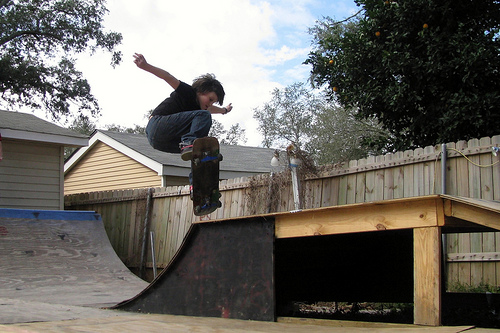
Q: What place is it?
A: It is a yard.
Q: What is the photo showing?
A: It is showing a yard.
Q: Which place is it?
A: It is a yard.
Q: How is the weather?
A: It is cloudy.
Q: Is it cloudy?
A: Yes, it is cloudy.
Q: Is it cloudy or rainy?
A: It is cloudy.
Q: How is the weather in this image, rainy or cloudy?
A: It is cloudy.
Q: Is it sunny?
A: No, it is cloudy.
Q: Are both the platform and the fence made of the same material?
A: Yes, both the platform and the fence are made of wood.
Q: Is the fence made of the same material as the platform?
A: Yes, both the fence and the platform are made of wood.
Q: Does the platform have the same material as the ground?
A: No, the platform is made of wood and the ground is made of metal.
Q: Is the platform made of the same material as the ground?
A: No, the platform is made of wood and the ground is made of metal.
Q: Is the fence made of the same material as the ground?
A: No, the fence is made of wood and the ground is made of metal.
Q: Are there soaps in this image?
A: No, there are no soaps.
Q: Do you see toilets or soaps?
A: No, there are no soaps or toilets.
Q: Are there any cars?
A: No, there are no cars.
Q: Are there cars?
A: No, there are no cars.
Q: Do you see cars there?
A: No, there are no cars.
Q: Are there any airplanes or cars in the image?
A: No, there are no cars or airplanes.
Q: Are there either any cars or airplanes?
A: No, there are no cars or airplanes.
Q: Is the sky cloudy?
A: Yes, the sky is cloudy.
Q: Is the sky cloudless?
A: No, the sky is cloudy.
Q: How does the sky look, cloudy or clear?
A: The sky is cloudy.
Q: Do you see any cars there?
A: No, there are no cars.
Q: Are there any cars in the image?
A: No, there are no cars.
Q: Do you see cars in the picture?
A: No, there are no cars.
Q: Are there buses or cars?
A: No, there are no cars or buses.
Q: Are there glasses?
A: No, there are no glasses.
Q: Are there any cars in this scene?
A: No, there are no cars.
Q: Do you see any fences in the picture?
A: Yes, there is a fence.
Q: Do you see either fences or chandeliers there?
A: Yes, there is a fence.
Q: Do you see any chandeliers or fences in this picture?
A: Yes, there is a fence.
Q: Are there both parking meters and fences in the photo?
A: No, there is a fence but no parking meters.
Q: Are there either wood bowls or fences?
A: Yes, there is a wood fence.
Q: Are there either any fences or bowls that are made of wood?
A: Yes, the fence is made of wood.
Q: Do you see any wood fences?
A: Yes, there is a fence that is made of wood.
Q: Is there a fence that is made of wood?
A: Yes, there is a fence that is made of wood.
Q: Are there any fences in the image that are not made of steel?
A: Yes, there is a fence that is made of wood.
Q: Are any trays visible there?
A: No, there are no trays.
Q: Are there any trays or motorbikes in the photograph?
A: No, there are no trays or motorbikes.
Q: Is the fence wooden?
A: Yes, the fence is wooden.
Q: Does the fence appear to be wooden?
A: Yes, the fence is wooden.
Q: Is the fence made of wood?
A: Yes, the fence is made of wood.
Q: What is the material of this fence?
A: The fence is made of wood.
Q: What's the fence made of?
A: The fence is made of wood.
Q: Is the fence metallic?
A: No, the fence is wooden.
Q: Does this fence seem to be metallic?
A: No, the fence is wooden.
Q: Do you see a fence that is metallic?
A: No, there is a fence but it is wooden.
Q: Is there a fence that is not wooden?
A: No, there is a fence but it is wooden.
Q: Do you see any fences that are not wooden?
A: No, there is a fence but it is wooden.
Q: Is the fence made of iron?
A: No, the fence is made of wood.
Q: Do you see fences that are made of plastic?
A: No, there is a fence but it is made of wood.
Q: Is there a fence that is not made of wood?
A: No, there is a fence but it is made of wood.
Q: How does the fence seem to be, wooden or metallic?
A: The fence is wooden.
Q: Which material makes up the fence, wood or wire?
A: The fence is made of wood.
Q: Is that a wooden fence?
A: Yes, that is a wooden fence.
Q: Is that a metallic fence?
A: No, that is a wooden fence.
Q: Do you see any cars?
A: No, there are no cars.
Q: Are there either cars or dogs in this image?
A: No, there are no cars or dogs.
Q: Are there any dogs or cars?
A: No, there are no cars or dogs.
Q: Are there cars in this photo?
A: No, there are no cars.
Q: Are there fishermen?
A: No, there are no fishermen.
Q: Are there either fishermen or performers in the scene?
A: No, there are no fishermen or performers.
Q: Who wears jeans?
A: The boy wears jeans.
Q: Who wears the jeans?
A: The boy wears jeans.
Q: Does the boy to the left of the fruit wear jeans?
A: Yes, the boy wears jeans.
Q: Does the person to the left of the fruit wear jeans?
A: Yes, the boy wears jeans.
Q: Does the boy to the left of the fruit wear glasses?
A: No, the boy wears jeans.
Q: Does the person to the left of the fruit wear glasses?
A: No, the boy wears jeans.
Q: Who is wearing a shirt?
A: The boy is wearing a shirt.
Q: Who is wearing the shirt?
A: The boy is wearing a shirt.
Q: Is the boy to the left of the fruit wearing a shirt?
A: Yes, the boy is wearing a shirt.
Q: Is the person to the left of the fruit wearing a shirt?
A: Yes, the boy is wearing a shirt.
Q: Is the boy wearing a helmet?
A: No, the boy is wearing a shirt.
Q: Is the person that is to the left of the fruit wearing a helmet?
A: No, the boy is wearing a shirt.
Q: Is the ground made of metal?
A: Yes, the ground is made of metal.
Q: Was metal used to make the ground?
A: Yes, the ground is made of metal.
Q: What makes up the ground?
A: The ground is made of metal.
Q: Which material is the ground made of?
A: The ground is made of metal.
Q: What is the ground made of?
A: The ground is made of metal.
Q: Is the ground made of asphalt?
A: No, the ground is made of metal.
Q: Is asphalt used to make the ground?
A: No, the ground is made of metal.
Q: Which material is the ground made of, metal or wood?
A: The ground is made of metal.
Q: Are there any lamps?
A: No, there are no lamps.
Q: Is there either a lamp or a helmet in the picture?
A: No, there are no lamps or helmets.